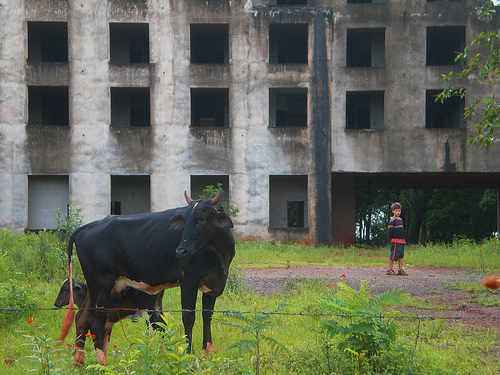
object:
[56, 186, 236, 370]
bull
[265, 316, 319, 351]
grass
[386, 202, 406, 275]
kid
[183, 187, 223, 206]
horns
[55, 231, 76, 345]
tail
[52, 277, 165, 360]
calf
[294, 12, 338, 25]
concrete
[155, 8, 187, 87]
wall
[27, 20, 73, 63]
window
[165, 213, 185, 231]
ear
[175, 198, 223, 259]
head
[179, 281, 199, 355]
leg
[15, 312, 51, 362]
flowers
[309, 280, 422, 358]
fern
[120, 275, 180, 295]
belly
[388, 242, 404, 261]
shorts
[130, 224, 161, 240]
rib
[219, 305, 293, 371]
bush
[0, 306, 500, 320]
wire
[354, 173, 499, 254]
gate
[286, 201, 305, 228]
door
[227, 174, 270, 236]
porch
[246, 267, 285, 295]
dirt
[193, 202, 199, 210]
spot